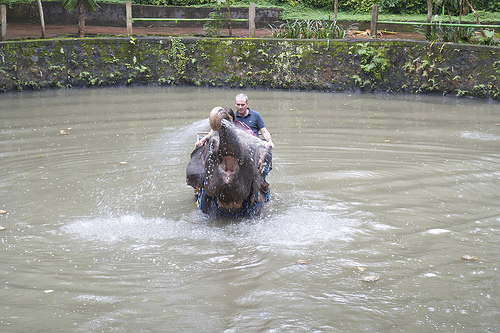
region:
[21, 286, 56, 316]
Ripples in the water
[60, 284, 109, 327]
Ripples in the water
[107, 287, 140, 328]
Ripples in the water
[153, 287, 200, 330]
Ripples in the water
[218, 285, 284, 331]
Ripples in the water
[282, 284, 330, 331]
Ripples in the water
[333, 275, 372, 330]
Ripples in the water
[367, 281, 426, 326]
Ripples in the water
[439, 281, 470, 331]
Ripples in the water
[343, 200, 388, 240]
Ripples in the water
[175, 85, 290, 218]
man riding elephant in enclosed body of water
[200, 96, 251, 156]
curled elephant trunk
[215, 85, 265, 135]
man in blue short sleeve shirt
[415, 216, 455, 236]
white froth on surface of water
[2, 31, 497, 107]
concrete edge of body of water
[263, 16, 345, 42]
green plant at concrete edge of water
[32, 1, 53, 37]
thin brown tree trunk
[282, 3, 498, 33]
patch of green grass beyond body of water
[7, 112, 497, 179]
round ripples emitting from elephant in water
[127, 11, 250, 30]
green rope stretched across wooden poles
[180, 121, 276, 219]
elephant splashing in the water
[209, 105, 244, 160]
elephant's grey trunk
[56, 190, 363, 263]
water being splashed around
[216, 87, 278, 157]
two people on elephant's back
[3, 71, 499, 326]
large pool of brown water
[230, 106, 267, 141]
man's navy polo style shirt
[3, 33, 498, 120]
short wall with grass growing on it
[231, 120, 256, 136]
person's red colored shirt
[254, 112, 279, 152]
man's left arm on the elephant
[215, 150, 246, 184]
elephant's open mouth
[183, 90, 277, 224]
man sits on back of elephant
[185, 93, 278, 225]
elephant stands in deep water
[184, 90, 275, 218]
Elephant opens mouth and sprays water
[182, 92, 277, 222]
elephant gets wet from being in the water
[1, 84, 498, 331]
water surrounds the elephant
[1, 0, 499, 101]
plants cover the embankment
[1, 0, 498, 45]
posts line the embankment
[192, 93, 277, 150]
man wears shirt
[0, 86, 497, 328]
ripples are created in the water from the elephant's movement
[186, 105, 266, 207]
elephant's mouth is open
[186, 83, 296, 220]
man sits on elephant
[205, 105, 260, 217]
elephant's trunk is raised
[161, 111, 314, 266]
elephant is in water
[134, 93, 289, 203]
elephant is spraying water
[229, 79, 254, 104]
man has bald head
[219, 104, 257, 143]
man has blue shirt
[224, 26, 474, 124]
dark grey dirt on bank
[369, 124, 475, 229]
water is dark grey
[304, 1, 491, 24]
green grass on hill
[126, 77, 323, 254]
elephant makes waves in water